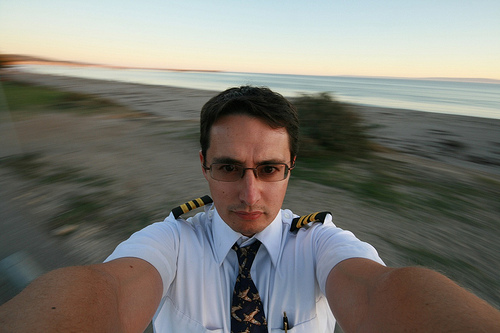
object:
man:
[0, 86, 500, 332]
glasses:
[202, 162, 295, 181]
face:
[204, 114, 292, 232]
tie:
[232, 239, 269, 332]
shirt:
[102, 194, 387, 333]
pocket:
[270, 314, 319, 332]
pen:
[282, 311, 290, 332]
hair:
[200, 86, 301, 173]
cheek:
[209, 178, 241, 197]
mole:
[220, 190, 225, 194]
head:
[197, 84, 301, 233]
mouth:
[230, 208, 269, 220]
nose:
[237, 168, 263, 207]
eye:
[219, 164, 239, 174]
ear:
[291, 152, 297, 169]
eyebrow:
[213, 155, 246, 165]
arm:
[0, 220, 179, 333]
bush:
[289, 92, 387, 166]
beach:
[0, 70, 500, 333]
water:
[15, 63, 499, 119]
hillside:
[0, 54, 74, 63]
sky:
[2, 1, 500, 79]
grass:
[0, 81, 63, 110]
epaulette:
[290, 211, 332, 231]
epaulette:
[170, 194, 216, 219]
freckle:
[51, 304, 56, 310]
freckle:
[128, 263, 133, 269]